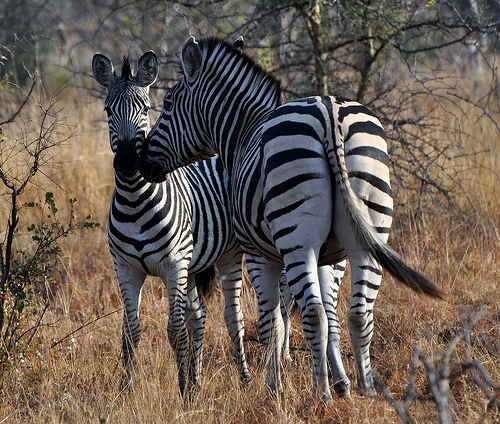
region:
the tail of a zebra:
[311, 108, 452, 308]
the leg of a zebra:
[288, 231, 335, 409]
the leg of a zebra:
[350, 225, 382, 394]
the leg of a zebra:
[248, 251, 289, 402]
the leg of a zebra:
[318, 269, 356, 406]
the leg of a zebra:
[164, 270, 194, 396]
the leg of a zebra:
[220, 252, 257, 384]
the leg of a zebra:
[116, 270, 146, 393]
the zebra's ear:
[90, 54, 117, 84]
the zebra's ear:
[133, 47, 162, 89]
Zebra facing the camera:
[61, 42, 267, 394]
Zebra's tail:
[282, 90, 445, 331]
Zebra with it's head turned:
[147, 36, 435, 401]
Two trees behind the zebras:
[234, 2, 489, 222]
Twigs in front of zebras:
[343, 307, 493, 419]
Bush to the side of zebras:
[0, 72, 78, 374]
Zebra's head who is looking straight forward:
[85, 39, 167, 186]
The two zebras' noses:
[88, 122, 185, 191]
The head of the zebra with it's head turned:
[147, 19, 281, 194]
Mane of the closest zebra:
[186, 23, 306, 121]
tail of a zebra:
[381, 251, 430, 291]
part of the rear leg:
[309, 299, 332, 353]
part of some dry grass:
[174, 362, 231, 419]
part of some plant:
[3, 271, 46, 307]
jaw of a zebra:
[176, 125, 203, 170]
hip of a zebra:
[348, 145, 400, 206]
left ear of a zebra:
[123, 45, 160, 87]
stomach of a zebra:
[203, 222, 232, 260]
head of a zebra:
[118, 73, 143, 128]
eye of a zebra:
[96, 96, 113, 119]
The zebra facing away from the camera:
[136, 30, 446, 400]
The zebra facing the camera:
[86, 50, 228, 387]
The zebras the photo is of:
[85, 36, 441, 402]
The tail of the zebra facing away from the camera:
[321, 99, 451, 299]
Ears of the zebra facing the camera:
[89, 43, 160, 90]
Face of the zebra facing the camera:
[99, 77, 156, 177]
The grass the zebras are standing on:
[7, 78, 489, 422]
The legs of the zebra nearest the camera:
[239, 240, 401, 400]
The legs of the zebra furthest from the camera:
[99, 254, 256, 385]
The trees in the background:
[6, 0, 491, 104]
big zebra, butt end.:
[268, 90, 400, 277]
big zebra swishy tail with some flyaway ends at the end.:
[329, 119, 449, 310]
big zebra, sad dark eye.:
[157, 95, 173, 110]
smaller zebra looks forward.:
[103, 101, 152, 117]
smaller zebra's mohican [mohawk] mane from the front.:
[116, 53, 137, 85]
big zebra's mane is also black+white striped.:
[174, 33, 286, 112]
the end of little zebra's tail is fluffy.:
[192, 260, 222, 306]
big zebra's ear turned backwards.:
[178, 33, 209, 93]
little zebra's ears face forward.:
[81, 48, 161, 92]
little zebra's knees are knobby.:
[114, 306, 255, 362]